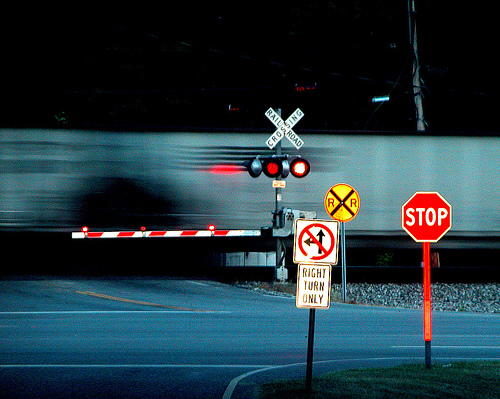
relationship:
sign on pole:
[320, 183, 362, 223] [336, 222, 353, 302]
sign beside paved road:
[399, 192, 451, 242] [0, 276, 499, 396]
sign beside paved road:
[323, 180, 360, 222] [0, 276, 499, 396]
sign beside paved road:
[291, 215, 341, 265] [0, 276, 499, 396]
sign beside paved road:
[294, 262, 330, 309] [0, 276, 499, 396]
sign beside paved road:
[263, 104, 303, 153] [0, 276, 499, 396]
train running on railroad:
[134, 146, 329, 243] [2, 245, 498, 278]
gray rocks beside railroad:
[438, 287, 498, 316] [2, 245, 498, 278]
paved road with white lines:
[37, 291, 285, 396] [86, 341, 158, 373]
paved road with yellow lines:
[37, 291, 285, 396] [113, 289, 163, 316]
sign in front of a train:
[399, 192, 451, 242] [72, 93, 483, 230]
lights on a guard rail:
[76, 222, 216, 232] [69, 229, 268, 241]